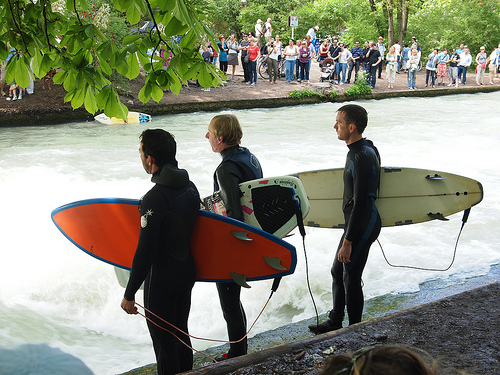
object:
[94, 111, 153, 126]
surf board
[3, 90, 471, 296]
water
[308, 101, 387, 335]
surfer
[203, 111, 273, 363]
surfer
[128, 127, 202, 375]
surfer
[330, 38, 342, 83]
spectators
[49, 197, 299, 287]
surf board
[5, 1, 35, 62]
branches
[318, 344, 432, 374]
hair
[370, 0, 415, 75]
tree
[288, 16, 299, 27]
sign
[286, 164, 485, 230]
surf board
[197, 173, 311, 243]
surf board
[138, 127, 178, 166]
hair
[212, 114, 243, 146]
hair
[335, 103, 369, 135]
hair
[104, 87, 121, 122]
leaves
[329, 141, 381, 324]
wetsuit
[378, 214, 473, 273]
cord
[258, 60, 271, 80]
tire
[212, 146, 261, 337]
wetsuit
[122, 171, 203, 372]
wetsuit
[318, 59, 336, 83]
stroller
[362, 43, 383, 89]
man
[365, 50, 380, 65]
shirt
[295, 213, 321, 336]
cord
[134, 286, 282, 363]
cord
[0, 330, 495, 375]
down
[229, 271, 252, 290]
fins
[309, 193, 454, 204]
line